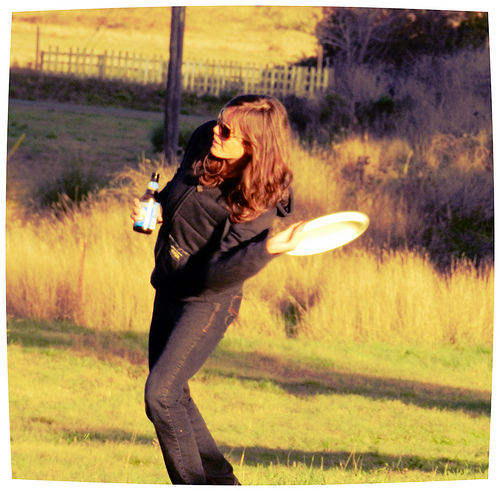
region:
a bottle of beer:
[132, 171, 166, 233]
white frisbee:
[288, 208, 370, 258]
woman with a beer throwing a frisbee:
[138, 91, 372, 483]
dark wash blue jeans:
[141, 279, 247, 487]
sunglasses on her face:
[213, 112, 250, 144]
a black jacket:
[150, 118, 290, 298]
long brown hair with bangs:
[193, 94, 297, 222]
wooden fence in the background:
[29, 42, 343, 106]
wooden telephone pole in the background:
[163, 5, 189, 165]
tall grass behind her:
[11, 129, 498, 354]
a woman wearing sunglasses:
[184, 80, 281, 174]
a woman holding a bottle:
[81, 72, 254, 261]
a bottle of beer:
[110, 172, 202, 263]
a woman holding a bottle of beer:
[108, 38, 263, 249]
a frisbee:
[249, 200, 444, 286]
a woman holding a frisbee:
[161, 81, 380, 312]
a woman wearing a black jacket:
[125, 101, 272, 291]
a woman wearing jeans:
[131, 84, 278, 480]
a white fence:
[9, 33, 398, 138]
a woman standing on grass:
[84, 78, 334, 486]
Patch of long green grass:
[24, 430, 67, 460]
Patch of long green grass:
[69, 428, 124, 476]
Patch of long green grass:
[231, 436, 265, 481]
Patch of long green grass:
[275, 430, 325, 487]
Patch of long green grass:
[325, 436, 370, 482]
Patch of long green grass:
[362, 431, 406, 480]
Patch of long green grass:
[406, 436, 457, 478]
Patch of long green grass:
[272, 411, 350, 466]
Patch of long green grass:
[343, 415, 417, 455]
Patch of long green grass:
[65, 375, 96, 422]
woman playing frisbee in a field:
[129, 91, 371, 486]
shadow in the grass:
[25, 423, 499, 473]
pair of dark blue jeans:
[143, 285, 243, 487]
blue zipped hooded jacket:
[153, 118, 294, 296]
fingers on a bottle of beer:
[129, 197, 141, 222]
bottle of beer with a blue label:
[133, 171, 164, 233]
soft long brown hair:
[191, 91, 294, 222]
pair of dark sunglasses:
[211, 114, 243, 141]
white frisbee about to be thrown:
[288, 211, 368, 253]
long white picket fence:
[37, 43, 337, 110]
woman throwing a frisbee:
[119, 76, 370, 488]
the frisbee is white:
[273, 202, 370, 257]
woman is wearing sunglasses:
[209, 112, 241, 143]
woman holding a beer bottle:
[123, 88, 374, 485]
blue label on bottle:
[128, 190, 161, 234]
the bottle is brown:
[130, 170, 167, 234]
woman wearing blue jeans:
[113, 94, 370, 484]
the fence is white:
[39, 45, 335, 100]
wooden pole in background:
[153, 7, 194, 155]